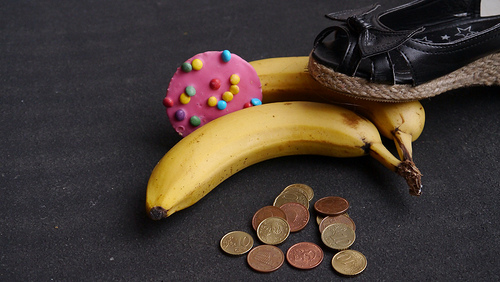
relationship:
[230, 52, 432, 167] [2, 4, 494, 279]
banana on a counter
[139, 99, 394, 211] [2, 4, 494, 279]
banana on a counter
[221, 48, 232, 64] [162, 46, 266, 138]
decoration on a cookie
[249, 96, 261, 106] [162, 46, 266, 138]
decoration on a cookie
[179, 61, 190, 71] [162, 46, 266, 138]
decoration on a cookie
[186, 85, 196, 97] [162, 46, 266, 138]
decoration on a cookie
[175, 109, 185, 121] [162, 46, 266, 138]
decoration on a cookie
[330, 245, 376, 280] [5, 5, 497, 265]
coin on a table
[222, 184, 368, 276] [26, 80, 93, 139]
coins on table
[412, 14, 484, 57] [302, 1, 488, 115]
stars inside shoes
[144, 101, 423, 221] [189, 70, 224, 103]
banana with candy topping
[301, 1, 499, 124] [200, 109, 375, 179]
black shoe on top of banana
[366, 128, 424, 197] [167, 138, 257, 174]
stem of banana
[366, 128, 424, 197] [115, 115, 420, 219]
stem of banana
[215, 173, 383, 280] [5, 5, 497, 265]
coins on table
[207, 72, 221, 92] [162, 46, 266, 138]
sprinkle on cookie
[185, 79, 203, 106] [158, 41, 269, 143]
sprinkle on cookie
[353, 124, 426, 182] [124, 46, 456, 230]
stem on bananas